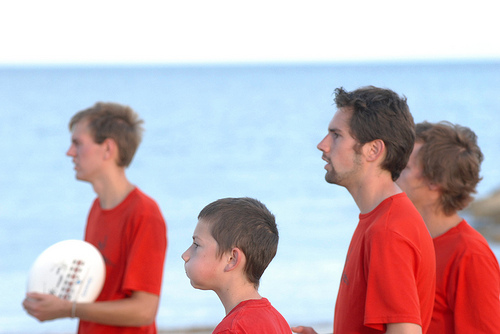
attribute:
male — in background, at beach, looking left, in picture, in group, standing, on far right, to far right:
[24, 104, 167, 333]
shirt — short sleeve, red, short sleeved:
[77, 187, 168, 332]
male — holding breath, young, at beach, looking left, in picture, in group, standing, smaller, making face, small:
[181, 198, 291, 333]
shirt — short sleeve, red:
[211, 298, 292, 333]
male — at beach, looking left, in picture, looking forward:
[318, 86, 438, 333]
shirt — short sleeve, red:
[333, 192, 437, 332]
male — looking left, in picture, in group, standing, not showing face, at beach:
[394, 123, 499, 333]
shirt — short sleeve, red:
[427, 220, 500, 333]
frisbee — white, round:
[27, 239, 106, 304]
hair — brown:
[335, 87, 418, 183]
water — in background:
[1, 61, 498, 333]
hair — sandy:
[69, 104, 140, 168]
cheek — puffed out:
[186, 255, 216, 286]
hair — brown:
[198, 198, 280, 289]